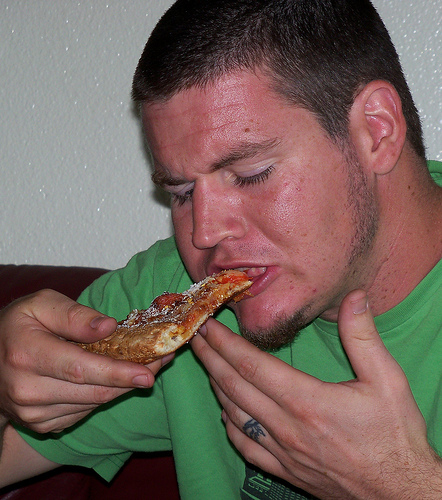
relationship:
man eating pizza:
[3, 1, 440, 496] [53, 269, 251, 364]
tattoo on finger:
[242, 417, 266, 443] [205, 379, 284, 450]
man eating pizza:
[3, 1, 440, 496] [69, 268, 255, 367]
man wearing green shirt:
[3, 1, 440, 496] [10, 161, 440, 498]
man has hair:
[3, 1, 440, 496] [135, 11, 431, 160]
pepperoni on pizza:
[151, 291, 195, 309] [69, 268, 255, 367]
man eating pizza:
[3, 1, 440, 496] [94, 260, 249, 358]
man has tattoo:
[3, 1, 440, 496] [242, 417, 266, 443]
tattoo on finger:
[242, 417, 266, 443] [210, 377, 277, 450]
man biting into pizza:
[3, 1, 440, 496] [69, 268, 255, 367]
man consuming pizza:
[3, 1, 440, 496] [69, 268, 255, 367]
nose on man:
[175, 179, 250, 254] [3, 1, 440, 496]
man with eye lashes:
[3, 1, 440, 496] [169, 167, 277, 201]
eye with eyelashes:
[168, 183, 193, 205] [172, 190, 194, 201]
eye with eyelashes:
[224, 157, 277, 186] [228, 169, 275, 184]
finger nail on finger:
[192, 322, 212, 338] [204, 334, 317, 393]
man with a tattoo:
[3, 1, 440, 496] [242, 416, 267, 443]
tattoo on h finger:
[242, 416, 267, 443] [205, 379, 279, 457]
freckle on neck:
[413, 192, 419, 197] [376, 173, 437, 298]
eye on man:
[224, 159, 279, 186] [99, 61, 366, 348]